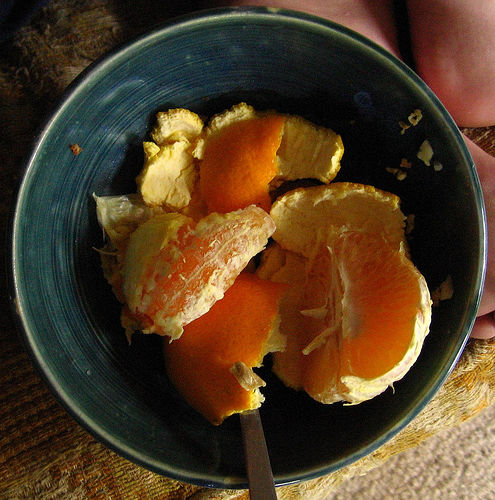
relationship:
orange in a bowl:
[104, 199, 437, 410] [13, 9, 481, 487]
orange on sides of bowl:
[104, 199, 437, 410] [13, 9, 481, 487]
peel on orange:
[215, 313, 258, 372] [104, 199, 437, 410]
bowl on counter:
[13, 9, 481, 487] [18, 431, 149, 495]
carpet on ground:
[17, 421, 488, 500] [104, 481, 426, 498]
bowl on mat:
[13, 9, 481, 487] [9, 439, 97, 484]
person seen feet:
[411, 2, 494, 334] [400, 12, 494, 129]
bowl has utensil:
[13, 9, 481, 487] [238, 408, 281, 499]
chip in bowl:
[414, 132, 450, 173] [13, 9, 481, 487]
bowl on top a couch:
[13, 9, 481, 487] [17, 421, 488, 500]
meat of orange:
[103, 196, 278, 339] [104, 199, 437, 410]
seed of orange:
[290, 296, 338, 363] [104, 199, 437, 410]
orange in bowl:
[104, 199, 437, 410] [13, 9, 481, 487]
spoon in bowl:
[238, 408, 281, 499] [13, 9, 481, 487]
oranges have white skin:
[104, 199, 437, 410] [116, 205, 185, 270]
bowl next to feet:
[13, 9, 481, 487] [411, 2, 494, 334]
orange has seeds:
[104, 199, 437, 410] [290, 296, 338, 363]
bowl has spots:
[13, 9, 481, 487] [378, 103, 457, 184]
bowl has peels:
[13, 9, 481, 487] [130, 103, 352, 208]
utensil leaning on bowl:
[238, 408, 281, 499] [13, 9, 481, 487]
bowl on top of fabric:
[13, 9, 481, 487] [17, 421, 488, 500]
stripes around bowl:
[19, 431, 126, 498] [13, 9, 481, 487]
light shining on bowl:
[473, 198, 494, 290] [13, 9, 481, 487]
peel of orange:
[194, 104, 289, 214] [104, 199, 437, 410]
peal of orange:
[287, 112, 348, 181] [104, 199, 437, 410]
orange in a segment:
[104, 199, 437, 410] [103, 196, 278, 339]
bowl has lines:
[13, 9, 481, 487] [68, 167, 96, 335]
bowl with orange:
[13, 9, 481, 487] [104, 199, 437, 410]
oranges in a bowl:
[104, 199, 437, 410] [13, 9, 481, 487]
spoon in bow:
[238, 408, 281, 499] [13, 9, 481, 487]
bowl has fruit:
[13, 9, 481, 487] [104, 199, 437, 410]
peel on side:
[194, 104, 289, 214] [104, 71, 375, 196]